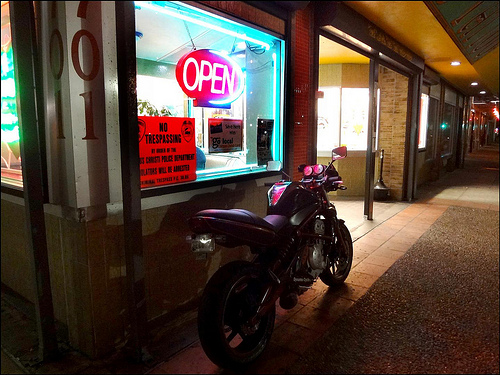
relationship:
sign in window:
[174, 47, 245, 107] [122, 0, 288, 193]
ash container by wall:
[370, 146, 392, 203] [362, 128, 420, 228]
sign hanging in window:
[138, 115, 197, 190] [134, 0, 284, 190]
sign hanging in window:
[174, 47, 245, 107] [134, 0, 284, 190]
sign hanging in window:
[208, 118, 243, 153] [134, 0, 284, 190]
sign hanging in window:
[258, 117, 274, 166] [134, 0, 284, 190]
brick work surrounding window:
[320, 63, 407, 196] [319, 82, 380, 152]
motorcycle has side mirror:
[186, 146, 352, 368] [330, 145, 347, 161]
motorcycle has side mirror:
[186, 146, 352, 368] [266, 160, 281, 171]